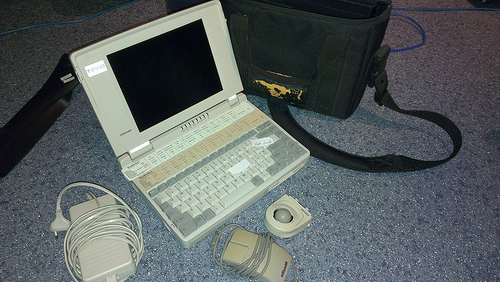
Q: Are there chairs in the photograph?
A: No, there are no chairs.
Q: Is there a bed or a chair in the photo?
A: No, there are no chairs or beds.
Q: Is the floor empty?
A: Yes, the floor is empty.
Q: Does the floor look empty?
A: Yes, the floor is empty.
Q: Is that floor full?
A: No, the floor is empty.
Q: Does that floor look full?
A: No, the floor is empty.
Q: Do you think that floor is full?
A: No, the floor is empty.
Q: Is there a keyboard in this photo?
A: Yes, there is a keyboard.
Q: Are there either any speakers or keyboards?
A: Yes, there is a keyboard.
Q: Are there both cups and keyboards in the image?
A: No, there is a keyboard but no cups.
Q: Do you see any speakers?
A: No, there are no speakers.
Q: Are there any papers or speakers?
A: No, there are no speakers or papers.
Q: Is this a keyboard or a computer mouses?
A: This is a keyboard.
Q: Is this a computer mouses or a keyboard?
A: This is a keyboard.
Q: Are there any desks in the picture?
A: No, there are no desks.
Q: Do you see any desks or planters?
A: No, there are no desks or planters.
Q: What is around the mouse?
A: The wire is around the mouse.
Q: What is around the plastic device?
A: The wire is around the mouse.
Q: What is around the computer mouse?
A: The wire is around the mouse.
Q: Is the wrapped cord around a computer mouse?
A: Yes, the cord is around a computer mouse.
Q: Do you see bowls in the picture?
A: No, there are no bowls.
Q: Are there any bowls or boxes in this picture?
A: No, there are no bowls or boxes.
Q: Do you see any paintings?
A: No, there are no paintings.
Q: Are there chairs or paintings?
A: No, there are no paintings or chairs.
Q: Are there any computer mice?
A: Yes, there is a computer mouse.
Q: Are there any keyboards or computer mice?
A: Yes, there is a computer mouse.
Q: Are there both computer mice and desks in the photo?
A: No, there is a computer mouse but no desks.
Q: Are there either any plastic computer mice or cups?
A: Yes, there is a plastic computer mouse.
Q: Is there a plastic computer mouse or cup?
A: Yes, there is a plastic computer mouse.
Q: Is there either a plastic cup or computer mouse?
A: Yes, there is a plastic computer mouse.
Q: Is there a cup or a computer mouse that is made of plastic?
A: Yes, the computer mouse is made of plastic.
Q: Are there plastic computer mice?
A: Yes, there is a computer mouse that is made of plastic.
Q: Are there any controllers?
A: No, there are no controllers.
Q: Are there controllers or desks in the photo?
A: No, there are no controllers or desks.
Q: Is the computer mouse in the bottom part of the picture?
A: Yes, the computer mouse is in the bottom of the image.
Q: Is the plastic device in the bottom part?
A: Yes, the computer mouse is in the bottom of the image.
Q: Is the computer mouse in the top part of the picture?
A: No, the computer mouse is in the bottom of the image.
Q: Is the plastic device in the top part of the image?
A: No, the computer mouse is in the bottom of the image.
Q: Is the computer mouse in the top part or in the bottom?
A: The computer mouse is in the bottom of the image.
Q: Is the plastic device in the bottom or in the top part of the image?
A: The computer mouse is in the bottom of the image.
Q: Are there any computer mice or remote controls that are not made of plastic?
A: No, there is a computer mouse but it is made of plastic.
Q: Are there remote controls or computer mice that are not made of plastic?
A: No, there is a computer mouse but it is made of plastic.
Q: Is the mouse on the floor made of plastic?
A: Yes, the computer mouse is made of plastic.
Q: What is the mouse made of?
A: The mouse is made of plastic.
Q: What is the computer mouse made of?
A: The mouse is made of plastic.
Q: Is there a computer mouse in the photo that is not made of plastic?
A: No, there is a computer mouse but it is made of plastic.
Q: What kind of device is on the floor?
A: The device is a computer mouse.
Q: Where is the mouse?
A: The mouse is on the floor.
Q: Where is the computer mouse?
A: The mouse is on the floor.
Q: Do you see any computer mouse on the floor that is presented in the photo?
A: Yes, there is a computer mouse on the floor.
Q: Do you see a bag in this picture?
A: Yes, there is a bag.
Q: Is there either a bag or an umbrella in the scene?
A: Yes, there is a bag.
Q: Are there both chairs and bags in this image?
A: No, there is a bag but no chairs.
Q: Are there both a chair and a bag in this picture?
A: No, there is a bag but no chairs.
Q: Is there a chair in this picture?
A: No, there are no chairs.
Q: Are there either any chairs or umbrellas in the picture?
A: No, there are no chairs or umbrellas.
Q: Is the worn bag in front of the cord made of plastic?
A: No, the bag is made of cloth.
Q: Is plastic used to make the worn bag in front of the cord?
A: No, the bag is made of cloth.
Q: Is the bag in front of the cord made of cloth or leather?
A: The bag is made of cloth.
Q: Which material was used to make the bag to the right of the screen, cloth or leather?
A: The bag is made of cloth.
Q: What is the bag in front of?
A: The bag is in front of the cord.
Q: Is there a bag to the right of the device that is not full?
A: Yes, there is a bag to the right of the screen.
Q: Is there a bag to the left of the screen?
A: No, the bag is to the right of the screen.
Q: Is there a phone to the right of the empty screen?
A: No, there is a bag to the right of the screen.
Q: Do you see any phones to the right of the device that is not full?
A: No, there is a bag to the right of the screen.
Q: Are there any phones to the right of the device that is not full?
A: No, there is a bag to the right of the screen.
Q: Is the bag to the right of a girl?
A: No, the bag is to the right of the screen.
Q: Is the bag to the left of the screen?
A: No, the bag is to the right of the screen.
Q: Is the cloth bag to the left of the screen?
A: No, the bag is to the right of the screen.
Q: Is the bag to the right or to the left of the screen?
A: The bag is to the right of the screen.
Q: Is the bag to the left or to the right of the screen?
A: The bag is to the right of the screen.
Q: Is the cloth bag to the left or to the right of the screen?
A: The bag is to the right of the screen.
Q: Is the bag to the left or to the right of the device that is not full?
A: The bag is to the right of the screen.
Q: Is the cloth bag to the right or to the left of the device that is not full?
A: The bag is to the right of the screen.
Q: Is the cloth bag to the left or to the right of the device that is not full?
A: The bag is to the right of the screen.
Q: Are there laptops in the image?
A: Yes, there is a laptop.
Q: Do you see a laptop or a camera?
A: Yes, there is a laptop.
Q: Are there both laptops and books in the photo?
A: No, there is a laptop but no books.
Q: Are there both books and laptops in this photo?
A: No, there is a laptop but no books.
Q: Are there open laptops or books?
A: Yes, there is an open laptop.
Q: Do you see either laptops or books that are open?
A: Yes, the laptop is open.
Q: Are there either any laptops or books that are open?
A: Yes, the laptop is open.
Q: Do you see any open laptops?
A: Yes, there is an open laptop.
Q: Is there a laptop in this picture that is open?
A: Yes, there is a laptop that is open.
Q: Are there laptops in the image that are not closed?
A: Yes, there is a open laptop.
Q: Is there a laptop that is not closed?
A: Yes, there is a open laptop.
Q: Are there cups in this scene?
A: No, there are no cups.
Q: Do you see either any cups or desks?
A: No, there are no cups or desks.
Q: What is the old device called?
A: The device is a laptop.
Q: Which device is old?
A: The device is a laptop.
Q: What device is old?
A: The device is a laptop.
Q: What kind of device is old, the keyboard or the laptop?
A: The laptop is old.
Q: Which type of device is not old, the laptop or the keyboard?
A: The keyboard is not old.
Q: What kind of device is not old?
A: The device is a keyboard.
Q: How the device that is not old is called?
A: The device is a keyboard.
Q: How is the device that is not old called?
A: The device is a keyboard.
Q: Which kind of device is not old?
A: The device is a keyboard.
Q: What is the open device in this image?
A: The device is a laptop.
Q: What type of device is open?
A: The device is a laptop.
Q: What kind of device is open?
A: The device is a laptop.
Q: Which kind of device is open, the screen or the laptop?
A: The laptop is open.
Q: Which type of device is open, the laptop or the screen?
A: The laptop is open.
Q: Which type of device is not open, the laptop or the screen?
A: The screen is not open.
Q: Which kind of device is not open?
A: The device is a screen.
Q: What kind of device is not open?
A: The device is a screen.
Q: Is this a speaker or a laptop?
A: This is a laptop.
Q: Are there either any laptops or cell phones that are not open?
A: No, there is a laptop but it is open.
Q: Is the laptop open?
A: Yes, the laptop is open.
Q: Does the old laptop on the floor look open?
A: Yes, the laptop computer is open.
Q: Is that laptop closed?
A: No, the laptop is open.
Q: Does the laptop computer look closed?
A: No, the laptop computer is open.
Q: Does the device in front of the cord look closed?
A: No, the laptop computer is open.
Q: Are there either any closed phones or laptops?
A: No, there is a laptop but it is open.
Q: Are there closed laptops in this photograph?
A: No, there is a laptop but it is open.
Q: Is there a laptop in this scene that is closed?
A: No, there is a laptop but it is open.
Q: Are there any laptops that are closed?
A: No, there is a laptop but it is open.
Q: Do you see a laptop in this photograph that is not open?
A: No, there is a laptop but it is open.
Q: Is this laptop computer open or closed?
A: The laptop computer is open.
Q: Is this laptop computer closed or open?
A: The laptop computer is open.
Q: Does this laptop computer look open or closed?
A: The laptop computer is open.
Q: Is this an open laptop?
A: Yes, this is an open laptop.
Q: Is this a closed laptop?
A: No, this is an open laptop.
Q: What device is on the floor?
A: The device is a laptop.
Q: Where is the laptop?
A: The laptop is on the floor.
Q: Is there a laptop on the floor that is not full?
A: Yes, there is a laptop on the floor.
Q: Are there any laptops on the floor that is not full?
A: Yes, there is a laptop on the floor.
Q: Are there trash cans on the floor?
A: No, there is a laptop on the floor.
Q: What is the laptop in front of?
A: The laptop is in front of the wire.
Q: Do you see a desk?
A: No, there are no desks.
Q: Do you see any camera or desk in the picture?
A: No, there are no desks or cameras.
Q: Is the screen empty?
A: Yes, the screen is empty.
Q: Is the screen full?
A: No, the screen is empty.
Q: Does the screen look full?
A: No, the screen is empty.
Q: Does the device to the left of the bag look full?
A: No, the screen is empty.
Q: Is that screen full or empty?
A: The screen is empty.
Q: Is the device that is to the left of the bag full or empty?
A: The screen is empty.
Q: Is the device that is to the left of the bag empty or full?
A: The screen is empty.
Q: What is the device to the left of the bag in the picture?
A: The device is a screen.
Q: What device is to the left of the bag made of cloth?
A: The device is a screen.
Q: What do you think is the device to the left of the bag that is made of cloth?
A: The device is a screen.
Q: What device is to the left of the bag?
A: The device is a screen.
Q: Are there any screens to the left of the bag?
A: Yes, there is a screen to the left of the bag.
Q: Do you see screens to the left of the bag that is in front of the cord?
A: Yes, there is a screen to the left of the bag.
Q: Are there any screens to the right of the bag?
A: No, the screen is to the left of the bag.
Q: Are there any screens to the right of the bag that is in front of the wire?
A: No, the screen is to the left of the bag.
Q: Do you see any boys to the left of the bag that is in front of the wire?
A: No, there is a screen to the left of the bag.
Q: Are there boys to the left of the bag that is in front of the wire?
A: No, there is a screen to the left of the bag.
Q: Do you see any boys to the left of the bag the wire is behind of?
A: No, there is a screen to the left of the bag.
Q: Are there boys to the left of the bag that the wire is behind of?
A: No, there is a screen to the left of the bag.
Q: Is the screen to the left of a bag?
A: Yes, the screen is to the left of a bag.